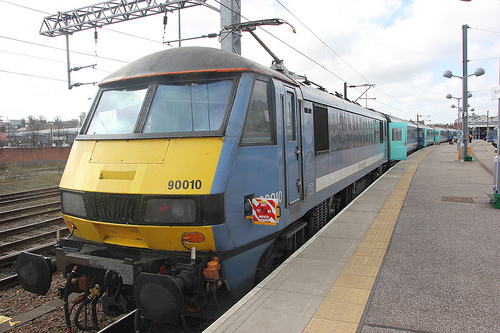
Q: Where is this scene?
A: A train station.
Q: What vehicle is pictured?
A: A train.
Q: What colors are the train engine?
A: Blue and yellow.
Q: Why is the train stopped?
A: To unload passengers.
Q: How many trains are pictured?
A: One.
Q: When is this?
A: Daytime.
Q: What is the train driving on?
A: The train tracks.